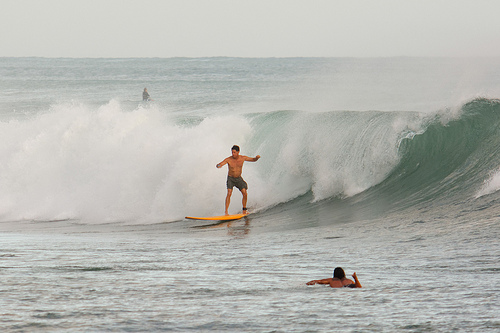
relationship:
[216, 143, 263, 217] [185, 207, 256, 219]
he standing on board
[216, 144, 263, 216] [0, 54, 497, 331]
he in ocean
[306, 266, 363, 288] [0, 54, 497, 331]
man in ocean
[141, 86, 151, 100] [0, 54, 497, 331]
person in ocean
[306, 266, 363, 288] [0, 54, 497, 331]
man swimming in ocean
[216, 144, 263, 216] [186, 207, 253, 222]
he on surfboard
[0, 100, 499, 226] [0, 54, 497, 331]
wave breaking in ocean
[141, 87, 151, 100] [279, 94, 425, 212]
person behind large wave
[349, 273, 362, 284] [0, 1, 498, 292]
foot in air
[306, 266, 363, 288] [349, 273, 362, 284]
man with foot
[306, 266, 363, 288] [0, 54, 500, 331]
man in water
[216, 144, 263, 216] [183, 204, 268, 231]
he on surfboard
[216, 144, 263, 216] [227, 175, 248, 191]
he in swim trunks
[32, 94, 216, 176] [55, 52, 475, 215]
spray on water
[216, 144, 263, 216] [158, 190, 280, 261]
he on surfboard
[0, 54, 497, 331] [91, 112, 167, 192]
ocean with wave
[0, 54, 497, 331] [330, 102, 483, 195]
ocean with wave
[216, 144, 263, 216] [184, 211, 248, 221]
he riding surfboard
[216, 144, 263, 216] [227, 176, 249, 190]
he in short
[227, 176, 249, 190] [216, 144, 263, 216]
short worn by he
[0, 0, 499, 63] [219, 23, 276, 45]
clouds in sky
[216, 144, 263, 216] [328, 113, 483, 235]
he surfs in ocean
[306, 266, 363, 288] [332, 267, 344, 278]
man has hair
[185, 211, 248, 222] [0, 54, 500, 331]
board on water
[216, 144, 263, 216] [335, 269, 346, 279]
he with hair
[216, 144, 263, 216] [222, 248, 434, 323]
he floating in water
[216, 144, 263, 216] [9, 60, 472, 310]
he in water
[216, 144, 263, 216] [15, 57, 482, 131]
he in distance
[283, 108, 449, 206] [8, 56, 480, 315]
wave on ocean